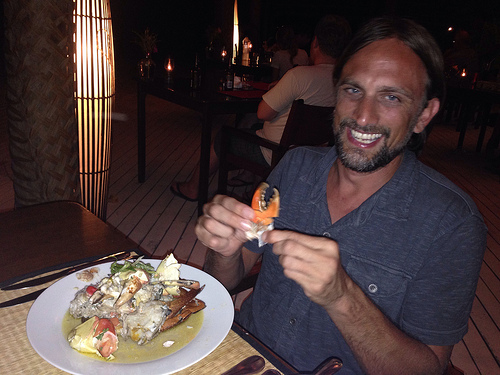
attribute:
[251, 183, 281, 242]
claw — cooked orange crustacean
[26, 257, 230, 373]
plate — big white , white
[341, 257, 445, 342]
button — shiny dark blue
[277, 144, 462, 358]
shirt — dark blue collared 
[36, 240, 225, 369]
plate — white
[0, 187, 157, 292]
folder — black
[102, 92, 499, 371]
floor — part , wooden 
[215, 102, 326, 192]
chair — part 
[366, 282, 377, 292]
shirt button — small shirt 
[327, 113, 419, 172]
beard — black , man's gray 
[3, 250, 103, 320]
utensil — silver